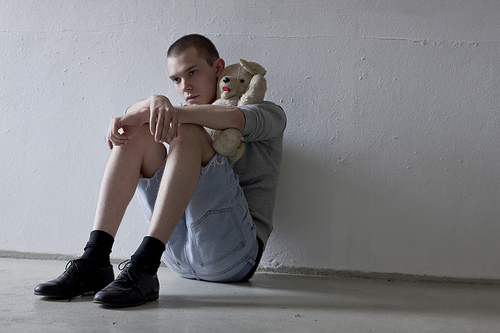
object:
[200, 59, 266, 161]
bear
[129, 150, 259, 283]
shorts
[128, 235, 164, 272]
socks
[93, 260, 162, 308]
shoes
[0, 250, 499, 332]
concrete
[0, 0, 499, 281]
wall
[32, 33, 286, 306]
boy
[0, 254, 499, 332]
floor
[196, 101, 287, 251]
shirt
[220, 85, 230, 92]
tongue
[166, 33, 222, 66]
hair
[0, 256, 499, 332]
cement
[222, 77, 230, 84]
nose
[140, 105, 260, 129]
arms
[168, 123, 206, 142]
knees